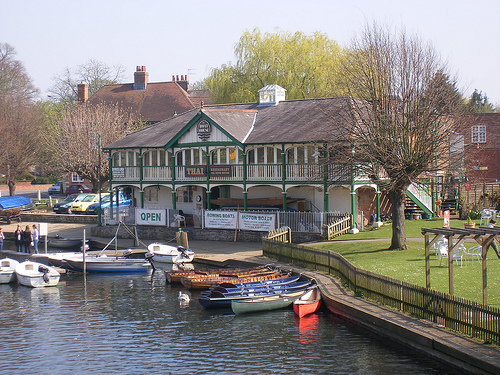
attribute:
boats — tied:
[165, 264, 323, 321]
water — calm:
[1, 256, 499, 374]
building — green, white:
[102, 86, 434, 232]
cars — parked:
[52, 193, 132, 215]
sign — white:
[133, 208, 168, 227]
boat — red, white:
[293, 285, 321, 318]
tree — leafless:
[300, 15, 487, 252]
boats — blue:
[198, 274, 315, 311]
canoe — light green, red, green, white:
[232, 289, 306, 314]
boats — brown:
[164, 264, 292, 289]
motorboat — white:
[147, 241, 194, 265]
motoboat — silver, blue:
[63, 254, 157, 274]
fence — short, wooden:
[261, 224, 500, 348]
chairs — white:
[430, 236, 485, 269]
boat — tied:
[17, 259, 61, 287]